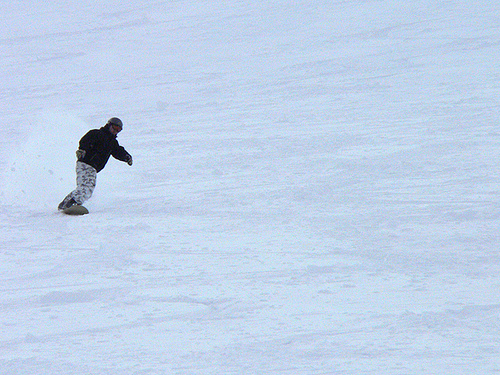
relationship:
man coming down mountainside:
[57, 116, 134, 215] [7, 8, 499, 373]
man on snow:
[57, 116, 134, 215] [9, 7, 493, 369]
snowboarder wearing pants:
[47, 111, 142, 218] [68, 157, 95, 208]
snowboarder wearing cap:
[64, 114, 134, 212] [103, 113, 120, 135]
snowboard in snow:
[53, 201, 85, 213] [9, 7, 493, 369]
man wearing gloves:
[57, 116, 134, 215] [73, 145, 138, 171]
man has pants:
[57, 116, 134, 215] [57, 161, 107, 206]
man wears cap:
[57, 116, 134, 215] [105, 116, 123, 129]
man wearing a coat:
[57, 116, 134, 215] [74, 127, 143, 167]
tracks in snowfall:
[12, 202, 160, 264] [2, 0, 499, 373]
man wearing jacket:
[57, 116, 134, 215] [50, 104, 156, 180]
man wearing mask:
[57, 116, 134, 215] [96, 107, 143, 137]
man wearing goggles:
[62, 116, 137, 212] [108, 123, 120, 133]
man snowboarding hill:
[57, 116, 134, 215] [4, 2, 499, 372]